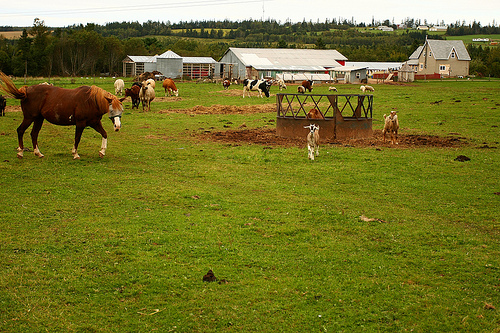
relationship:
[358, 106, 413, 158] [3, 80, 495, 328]
animal in field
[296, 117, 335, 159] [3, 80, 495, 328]
animal in field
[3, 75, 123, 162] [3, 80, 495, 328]
animal in field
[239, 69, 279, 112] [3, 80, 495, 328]
animal in field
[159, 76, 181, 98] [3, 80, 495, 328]
animal in field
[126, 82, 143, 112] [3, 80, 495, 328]
animal in field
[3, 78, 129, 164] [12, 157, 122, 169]
brown horse on grass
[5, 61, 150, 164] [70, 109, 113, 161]
horse has legs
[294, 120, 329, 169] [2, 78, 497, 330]
goats on grass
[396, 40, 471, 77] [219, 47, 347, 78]
house next to barn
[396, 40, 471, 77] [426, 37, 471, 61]
house has roof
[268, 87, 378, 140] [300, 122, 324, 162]
pen next to goat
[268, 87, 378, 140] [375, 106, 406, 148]
pen next to goat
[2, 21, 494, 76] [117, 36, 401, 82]
green trees are behind barn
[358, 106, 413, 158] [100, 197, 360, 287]
animal in field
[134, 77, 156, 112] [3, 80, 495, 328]
animal in field